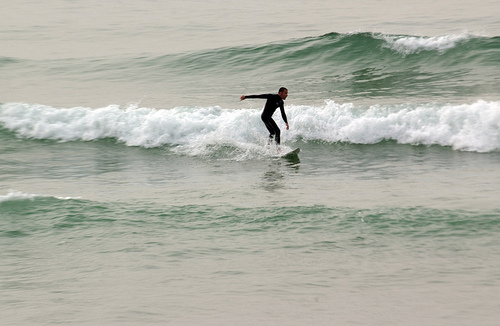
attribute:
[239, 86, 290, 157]
surfer — standing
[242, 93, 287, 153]
wetsuit — black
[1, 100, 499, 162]
wave — broken, the biggest, white, large, rolling, foamy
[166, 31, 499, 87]
wave — cresting, large, green, about to crest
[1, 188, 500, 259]
wave — small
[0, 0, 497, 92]
water — calm, green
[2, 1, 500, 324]
water — green blue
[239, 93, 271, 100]
arm — extended, left arm, outstretched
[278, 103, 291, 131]
arm — hanging down'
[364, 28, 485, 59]
top — white